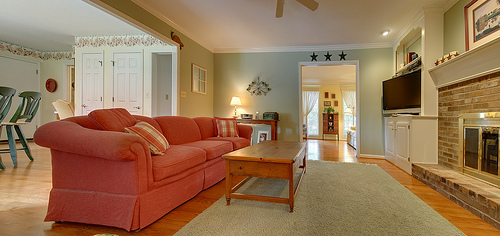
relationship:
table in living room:
[224, 136, 309, 210] [0, 0, 500, 235]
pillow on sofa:
[125, 120, 167, 154] [35, 107, 276, 230]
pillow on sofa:
[214, 114, 240, 136] [35, 107, 276, 230]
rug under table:
[170, 163, 461, 234] [224, 136, 309, 210]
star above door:
[338, 51, 348, 60] [298, 59, 359, 164]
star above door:
[324, 50, 333, 63] [298, 59, 359, 164]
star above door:
[309, 51, 320, 62] [298, 59, 359, 164]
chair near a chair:
[3, 88, 42, 166] [0, 84, 20, 168]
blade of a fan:
[275, 0, 286, 17] [248, 0, 321, 20]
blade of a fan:
[291, 0, 320, 11] [248, 0, 321, 20]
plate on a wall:
[45, 78, 56, 94] [43, 53, 73, 129]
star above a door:
[338, 51, 348, 60] [298, 59, 359, 164]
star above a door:
[324, 50, 333, 63] [298, 59, 359, 164]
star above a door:
[309, 51, 320, 62] [298, 59, 359, 164]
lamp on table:
[229, 94, 243, 118] [236, 116, 278, 140]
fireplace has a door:
[437, 74, 498, 192] [457, 111, 498, 187]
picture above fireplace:
[464, 0, 500, 52] [437, 74, 498, 192]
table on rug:
[224, 136, 309, 210] [170, 163, 461, 234]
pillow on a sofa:
[125, 120, 167, 154] [35, 107, 276, 230]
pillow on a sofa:
[214, 114, 240, 136] [35, 107, 276, 230]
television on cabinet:
[382, 68, 425, 112] [382, 115, 437, 175]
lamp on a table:
[229, 94, 243, 118] [236, 116, 278, 140]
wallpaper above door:
[0, 34, 170, 56] [112, 50, 144, 113]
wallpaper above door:
[0, 34, 170, 56] [81, 51, 107, 115]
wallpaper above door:
[0, 34, 170, 56] [0, 59, 39, 143]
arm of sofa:
[35, 120, 141, 160] [35, 107, 276, 230]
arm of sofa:
[232, 125, 254, 136] [35, 107, 276, 230]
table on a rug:
[224, 136, 309, 210] [170, 163, 461, 234]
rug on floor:
[170, 163, 461, 234] [0, 141, 500, 234]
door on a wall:
[298, 59, 359, 164] [217, 47, 396, 158]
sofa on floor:
[35, 107, 276, 230] [0, 141, 500, 234]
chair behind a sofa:
[3, 88, 42, 166] [35, 107, 276, 230]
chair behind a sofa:
[0, 84, 20, 168] [35, 107, 276, 230]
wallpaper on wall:
[0, 34, 170, 56] [43, 53, 73, 129]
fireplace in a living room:
[437, 74, 498, 192] [0, 0, 500, 235]